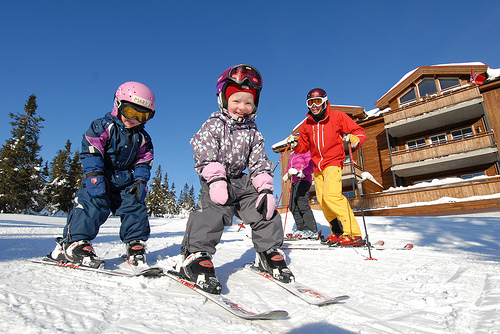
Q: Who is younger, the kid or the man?
A: The kid is younger than the man.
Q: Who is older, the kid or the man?
A: The man is older than the kid.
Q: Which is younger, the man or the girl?
A: The girl is younger than the man.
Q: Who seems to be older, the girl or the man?
A: The man is older than the girl.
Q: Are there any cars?
A: No, there are no cars.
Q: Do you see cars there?
A: No, there are no cars.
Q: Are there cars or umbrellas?
A: No, there are no cars or umbrellas.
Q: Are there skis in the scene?
A: Yes, there are skis.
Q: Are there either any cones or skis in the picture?
A: Yes, there are skis.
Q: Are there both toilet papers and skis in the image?
A: No, there are skis but no toilet papers.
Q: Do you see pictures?
A: No, there are no pictures.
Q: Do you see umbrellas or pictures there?
A: No, there are no pictures or umbrellas.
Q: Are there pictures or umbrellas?
A: No, there are no pictures or umbrellas.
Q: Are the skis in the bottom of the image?
A: Yes, the skis are in the bottom of the image.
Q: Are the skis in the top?
A: No, the skis are in the bottom of the image.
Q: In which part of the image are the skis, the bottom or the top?
A: The skis are in the bottom of the image.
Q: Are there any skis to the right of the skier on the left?
A: Yes, there are skis to the right of the skier.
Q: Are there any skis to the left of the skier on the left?
A: No, the skis are to the right of the skier.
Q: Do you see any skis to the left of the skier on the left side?
A: No, the skis are to the right of the skier.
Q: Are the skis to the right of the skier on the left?
A: Yes, the skis are to the right of the skier.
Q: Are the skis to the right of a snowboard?
A: No, the skis are to the right of the skier.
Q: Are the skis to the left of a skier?
A: No, the skis are to the right of a skier.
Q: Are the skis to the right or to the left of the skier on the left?
A: The skis are to the right of the skier.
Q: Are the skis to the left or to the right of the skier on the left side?
A: The skis are to the right of the skier.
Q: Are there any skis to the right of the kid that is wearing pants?
A: Yes, there are skis to the right of the child.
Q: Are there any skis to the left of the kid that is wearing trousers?
A: No, the skis are to the right of the child.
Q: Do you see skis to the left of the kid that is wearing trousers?
A: No, the skis are to the right of the child.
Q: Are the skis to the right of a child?
A: Yes, the skis are to the right of a child.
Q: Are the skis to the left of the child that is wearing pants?
A: No, the skis are to the right of the kid.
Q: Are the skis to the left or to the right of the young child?
A: The skis are to the right of the kid.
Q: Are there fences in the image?
A: No, there are no fences.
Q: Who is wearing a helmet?
A: The man is wearing a helmet.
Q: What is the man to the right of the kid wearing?
A: The man is wearing a helmet.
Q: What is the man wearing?
A: The man is wearing a helmet.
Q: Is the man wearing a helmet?
A: Yes, the man is wearing a helmet.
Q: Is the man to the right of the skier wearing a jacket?
A: No, the man is wearing a helmet.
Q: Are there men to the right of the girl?
A: Yes, there is a man to the right of the girl.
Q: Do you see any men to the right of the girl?
A: Yes, there is a man to the right of the girl.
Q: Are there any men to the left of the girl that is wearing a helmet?
A: No, the man is to the right of the girl.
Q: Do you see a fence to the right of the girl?
A: No, there is a man to the right of the girl.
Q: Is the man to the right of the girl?
A: Yes, the man is to the right of the girl.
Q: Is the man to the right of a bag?
A: No, the man is to the right of the girl.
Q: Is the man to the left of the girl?
A: No, the man is to the right of the girl.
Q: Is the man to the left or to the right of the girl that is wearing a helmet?
A: The man is to the right of the girl.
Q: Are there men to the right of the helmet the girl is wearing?
A: Yes, there is a man to the right of the helmet.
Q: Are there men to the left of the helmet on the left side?
A: No, the man is to the right of the helmet.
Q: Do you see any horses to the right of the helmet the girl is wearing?
A: No, there is a man to the right of the helmet.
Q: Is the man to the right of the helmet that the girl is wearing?
A: Yes, the man is to the right of the helmet.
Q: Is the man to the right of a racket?
A: No, the man is to the right of the helmet.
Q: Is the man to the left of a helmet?
A: No, the man is to the right of a helmet.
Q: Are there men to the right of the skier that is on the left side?
A: Yes, there is a man to the right of the skier.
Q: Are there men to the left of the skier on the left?
A: No, the man is to the right of the skier.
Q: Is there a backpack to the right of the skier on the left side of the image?
A: No, there is a man to the right of the skier.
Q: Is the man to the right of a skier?
A: Yes, the man is to the right of a skier.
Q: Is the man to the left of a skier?
A: No, the man is to the right of a skier.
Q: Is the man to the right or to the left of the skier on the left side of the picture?
A: The man is to the right of the skier.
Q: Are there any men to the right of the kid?
A: Yes, there is a man to the right of the kid.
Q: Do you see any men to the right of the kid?
A: Yes, there is a man to the right of the kid.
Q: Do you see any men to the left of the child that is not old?
A: No, the man is to the right of the kid.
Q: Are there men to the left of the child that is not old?
A: No, the man is to the right of the kid.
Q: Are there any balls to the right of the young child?
A: No, there is a man to the right of the child.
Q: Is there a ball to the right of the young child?
A: No, there is a man to the right of the child.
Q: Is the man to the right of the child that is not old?
A: Yes, the man is to the right of the kid.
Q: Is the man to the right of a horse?
A: No, the man is to the right of the kid.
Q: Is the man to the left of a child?
A: No, the man is to the right of a child.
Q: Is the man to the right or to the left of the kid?
A: The man is to the right of the kid.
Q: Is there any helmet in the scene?
A: Yes, there is a helmet.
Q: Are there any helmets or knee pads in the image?
A: Yes, there is a helmet.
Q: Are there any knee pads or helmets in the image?
A: Yes, there is a helmet.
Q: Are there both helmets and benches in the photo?
A: No, there is a helmet but no benches.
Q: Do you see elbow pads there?
A: No, there are no elbow pads.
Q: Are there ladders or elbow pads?
A: No, there are no elbow pads or ladders.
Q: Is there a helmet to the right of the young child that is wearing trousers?
A: Yes, there is a helmet to the right of the kid.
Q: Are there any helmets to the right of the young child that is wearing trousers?
A: Yes, there is a helmet to the right of the kid.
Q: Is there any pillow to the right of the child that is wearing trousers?
A: No, there is a helmet to the right of the kid.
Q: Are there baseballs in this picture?
A: No, there are no baseballs.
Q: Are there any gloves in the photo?
A: Yes, there are gloves.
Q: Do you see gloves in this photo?
A: Yes, there are gloves.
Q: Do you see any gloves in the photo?
A: Yes, there are gloves.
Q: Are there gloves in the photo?
A: Yes, there are gloves.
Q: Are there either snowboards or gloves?
A: Yes, there are gloves.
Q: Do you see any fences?
A: No, there are no fences.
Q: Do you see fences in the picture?
A: No, there are no fences.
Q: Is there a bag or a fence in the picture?
A: No, there are no fences or bags.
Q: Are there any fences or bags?
A: No, there are no fences or bags.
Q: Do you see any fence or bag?
A: No, there are no fences or bags.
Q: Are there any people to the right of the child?
A: Yes, there is a person to the right of the child.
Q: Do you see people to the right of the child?
A: Yes, there is a person to the right of the child.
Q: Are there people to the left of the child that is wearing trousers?
A: No, the person is to the right of the child.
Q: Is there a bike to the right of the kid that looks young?
A: No, there is a person to the right of the kid.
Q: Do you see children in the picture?
A: Yes, there is a child.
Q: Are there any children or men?
A: Yes, there is a child.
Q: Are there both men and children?
A: Yes, there are both a child and a man.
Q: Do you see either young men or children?
A: Yes, there is a young child.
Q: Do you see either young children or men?
A: Yes, there is a young child.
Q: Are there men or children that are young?
A: Yes, the child is young.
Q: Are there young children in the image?
A: Yes, there is a young child.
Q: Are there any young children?
A: Yes, there is a young child.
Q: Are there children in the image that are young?
A: Yes, there is a child that is young.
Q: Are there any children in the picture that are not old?
A: Yes, there is an young child.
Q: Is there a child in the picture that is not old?
A: Yes, there is an young child.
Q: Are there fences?
A: No, there are no fences.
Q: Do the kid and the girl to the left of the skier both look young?
A: Yes, both the kid and the girl are young.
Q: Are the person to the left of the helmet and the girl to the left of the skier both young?
A: Yes, both the kid and the girl are young.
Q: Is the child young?
A: Yes, the child is young.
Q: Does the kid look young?
A: Yes, the kid is young.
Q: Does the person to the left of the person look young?
A: Yes, the kid is young.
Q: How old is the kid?
A: The kid is young.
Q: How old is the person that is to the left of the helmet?
A: The kid is young.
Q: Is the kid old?
A: No, the kid is young.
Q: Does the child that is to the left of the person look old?
A: No, the child is young.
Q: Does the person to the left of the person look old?
A: No, the child is young.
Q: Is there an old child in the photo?
A: No, there is a child but he is young.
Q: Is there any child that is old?
A: No, there is a child but he is young.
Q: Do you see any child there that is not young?
A: No, there is a child but he is young.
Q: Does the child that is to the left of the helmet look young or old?
A: The kid is young.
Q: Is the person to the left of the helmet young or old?
A: The kid is young.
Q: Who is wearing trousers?
A: The kid is wearing trousers.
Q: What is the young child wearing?
A: The kid is wearing trousers.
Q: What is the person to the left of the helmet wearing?
A: The kid is wearing trousers.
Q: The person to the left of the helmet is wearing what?
A: The kid is wearing trousers.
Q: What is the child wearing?
A: The kid is wearing trousers.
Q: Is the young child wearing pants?
A: Yes, the kid is wearing pants.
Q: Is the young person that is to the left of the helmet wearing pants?
A: Yes, the kid is wearing pants.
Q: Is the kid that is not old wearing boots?
A: No, the kid is wearing pants.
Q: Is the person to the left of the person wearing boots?
A: No, the kid is wearing pants.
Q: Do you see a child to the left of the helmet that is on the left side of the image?
A: No, the child is to the right of the helmet.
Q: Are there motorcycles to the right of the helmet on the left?
A: No, there is a child to the right of the helmet.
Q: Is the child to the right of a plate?
A: No, the child is to the right of the helmet.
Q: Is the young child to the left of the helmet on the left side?
A: No, the child is to the right of the helmet.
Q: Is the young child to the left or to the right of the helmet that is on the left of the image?
A: The child is to the right of the helmet.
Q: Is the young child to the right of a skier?
A: No, the kid is to the left of a skier.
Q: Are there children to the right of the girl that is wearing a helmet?
A: Yes, there is a child to the right of the girl.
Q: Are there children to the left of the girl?
A: No, the child is to the right of the girl.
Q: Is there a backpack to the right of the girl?
A: No, there is a child to the right of the girl.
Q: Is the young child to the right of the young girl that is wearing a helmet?
A: Yes, the child is to the right of the girl.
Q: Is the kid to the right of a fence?
A: No, the kid is to the right of the girl.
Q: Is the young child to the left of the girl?
A: No, the child is to the right of the girl.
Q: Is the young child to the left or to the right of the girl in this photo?
A: The child is to the right of the girl.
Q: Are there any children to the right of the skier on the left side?
A: Yes, there is a child to the right of the skier.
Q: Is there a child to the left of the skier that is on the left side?
A: No, the child is to the right of the skier.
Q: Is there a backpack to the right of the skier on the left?
A: No, there is a child to the right of the skier.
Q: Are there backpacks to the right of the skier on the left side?
A: No, there is a child to the right of the skier.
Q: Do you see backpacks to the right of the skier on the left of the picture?
A: No, there is a child to the right of the skier.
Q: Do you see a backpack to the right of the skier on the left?
A: No, there is a child to the right of the skier.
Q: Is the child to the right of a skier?
A: Yes, the child is to the right of a skier.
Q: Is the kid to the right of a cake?
A: No, the kid is to the right of a skier.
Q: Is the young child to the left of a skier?
A: No, the kid is to the right of a skier.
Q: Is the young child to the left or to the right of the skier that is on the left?
A: The kid is to the right of the skier.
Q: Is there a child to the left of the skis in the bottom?
A: Yes, there is a child to the left of the skis.